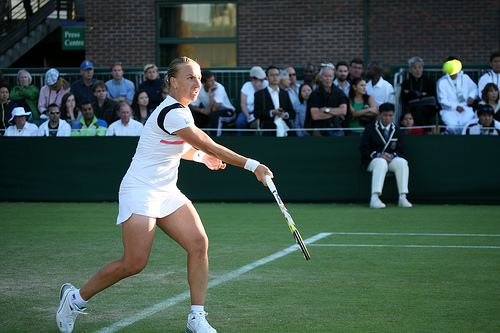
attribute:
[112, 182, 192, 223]
skirt — white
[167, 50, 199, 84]
hair — blond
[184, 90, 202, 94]
womans mouth — open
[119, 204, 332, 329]
line — white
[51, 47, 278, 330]
woman — young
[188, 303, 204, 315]
socks — white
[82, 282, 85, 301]
socks — white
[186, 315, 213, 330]
sneakers — white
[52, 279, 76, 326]
sneakers — white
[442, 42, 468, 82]
ball — tennis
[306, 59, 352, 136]
man — folded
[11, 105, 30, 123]
hat — white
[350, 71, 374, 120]
woman — green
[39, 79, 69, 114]
shirt — pink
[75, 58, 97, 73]
hat — blue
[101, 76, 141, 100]
shirt — button down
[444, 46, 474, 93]
ball — tennis, inflight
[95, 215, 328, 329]
line — white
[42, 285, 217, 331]
shoes — tennis, white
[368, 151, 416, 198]
pants — white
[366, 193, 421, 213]
shoes — white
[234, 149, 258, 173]
band — white, wrist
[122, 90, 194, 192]
shirt — red, white, tennis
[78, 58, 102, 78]
hat — blue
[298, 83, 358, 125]
shirt — black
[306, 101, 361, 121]
arms — crossed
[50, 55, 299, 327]
player — tennis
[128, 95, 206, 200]
shirt — white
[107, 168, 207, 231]
skirt — white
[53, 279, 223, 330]
shoes — white, tennis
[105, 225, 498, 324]
lines — white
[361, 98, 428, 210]
man — sitting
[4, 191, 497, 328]
court — tennis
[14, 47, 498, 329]
match — tennis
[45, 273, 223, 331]
shoes — pair, white, tennis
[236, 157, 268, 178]
wristband — white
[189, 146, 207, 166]
wristband — white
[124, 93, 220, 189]
shirt — white, short sleeve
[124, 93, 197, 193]
shirt — white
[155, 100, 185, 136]
stripe — black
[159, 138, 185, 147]
stripe — red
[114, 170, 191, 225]
skirt — white, tennis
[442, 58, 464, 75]
ball — yellow, tennis